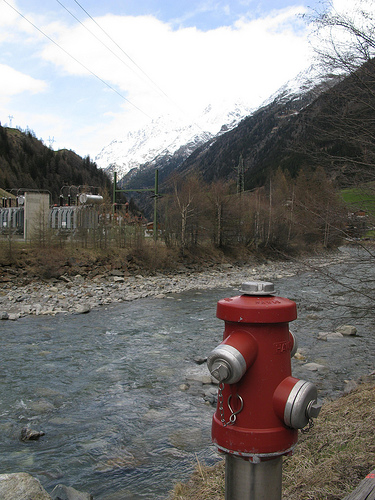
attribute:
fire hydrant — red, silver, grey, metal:
[206, 281, 322, 500]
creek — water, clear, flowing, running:
[0, 246, 374, 499]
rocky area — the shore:
[0, 252, 351, 320]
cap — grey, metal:
[238, 281, 277, 296]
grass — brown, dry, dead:
[165, 375, 374, 499]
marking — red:
[364, 472, 374, 479]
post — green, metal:
[153, 169, 159, 242]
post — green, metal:
[111, 172, 117, 214]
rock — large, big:
[317, 330, 344, 341]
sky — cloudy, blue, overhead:
[0, 0, 374, 161]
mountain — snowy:
[129, 49, 365, 221]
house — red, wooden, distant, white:
[141, 219, 166, 237]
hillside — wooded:
[0, 126, 161, 224]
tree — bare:
[268, 0, 374, 350]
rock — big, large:
[335, 324, 357, 336]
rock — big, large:
[301, 362, 327, 372]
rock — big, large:
[193, 355, 208, 364]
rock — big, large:
[186, 373, 220, 385]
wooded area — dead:
[0, 167, 352, 283]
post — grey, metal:
[225, 454, 283, 500]